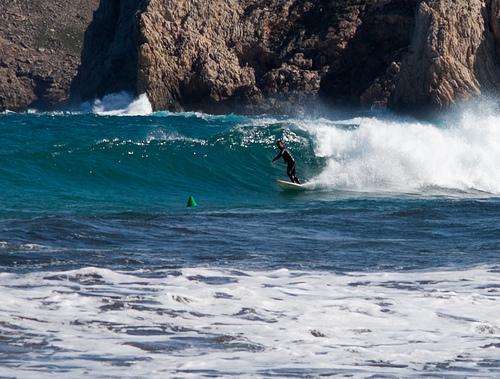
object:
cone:
[187, 196, 198, 207]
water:
[0, 89, 499, 378]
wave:
[0, 93, 499, 212]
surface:
[0, 198, 500, 379]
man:
[271, 141, 302, 184]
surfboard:
[277, 179, 306, 191]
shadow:
[69, 0, 154, 120]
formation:
[0, 0, 499, 117]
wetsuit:
[273, 148, 302, 185]